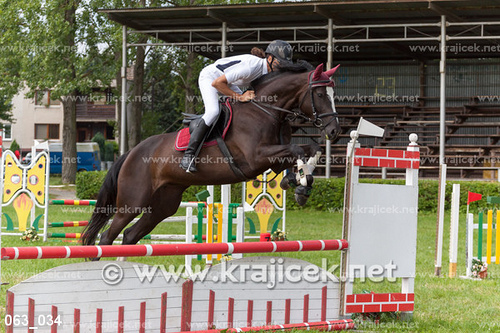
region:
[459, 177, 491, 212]
The flag is red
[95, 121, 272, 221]
The horse is dark brown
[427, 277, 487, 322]
The grass is green and long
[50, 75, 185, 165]
The trees are in the back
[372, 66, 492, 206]
The bleachers are empty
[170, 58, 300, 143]
The jockey has on white clothes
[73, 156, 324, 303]
The horse is jumping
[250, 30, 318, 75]
The jockey has a helmet on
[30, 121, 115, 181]
The van is parked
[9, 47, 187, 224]
Buildings are in the back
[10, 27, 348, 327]
horse and rider jumping over red pole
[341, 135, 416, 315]
white panel with bricks painted on top and bottom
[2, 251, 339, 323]
spaced red vertical lines on curved white panels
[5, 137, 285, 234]
yellow butterfly supports at end of poles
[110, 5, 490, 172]
dark roof and metal supports over wooden stands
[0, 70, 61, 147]
tan building with windows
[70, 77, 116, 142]
brown terrace over recessed entry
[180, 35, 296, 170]
rider in white outfit with black boots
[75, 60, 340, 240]
dark brown horse with covered red ears and red padding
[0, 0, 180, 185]
pale sky through tree branches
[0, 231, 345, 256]
a long red and white pole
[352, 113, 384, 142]
a small white flag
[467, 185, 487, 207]
a small red flag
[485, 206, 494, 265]
a tall yellow pole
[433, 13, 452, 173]
a tall gray pole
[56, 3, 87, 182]
a tall gray tree trunk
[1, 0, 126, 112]
green tree leaves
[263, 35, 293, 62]
a black helmet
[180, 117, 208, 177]
a woman's black boot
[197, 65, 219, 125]
the leg of a woman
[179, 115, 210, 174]
black boot on the rider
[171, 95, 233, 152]
black and red saddle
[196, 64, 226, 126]
white pants on the rider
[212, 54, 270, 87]
white and black shirt on the rider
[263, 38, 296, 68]
black helmet on the rider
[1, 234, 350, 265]
red jumping bar under the horse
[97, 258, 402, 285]
clear watermark logo across the photo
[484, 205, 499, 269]
yellow jump planks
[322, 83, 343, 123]
white mark on the horse's head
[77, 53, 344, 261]
brown horse with it's rider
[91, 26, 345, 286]
Large horse leaping in the air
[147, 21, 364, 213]
Small jokey on a horse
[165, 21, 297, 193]
Woman wearing riding boots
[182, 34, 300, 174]
Woman wearing black hat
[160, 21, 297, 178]
Woman wearing white shirt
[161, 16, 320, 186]
Woman wearing white pants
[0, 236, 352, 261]
Red and white pole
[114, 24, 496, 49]
Large metal posts on a buiolding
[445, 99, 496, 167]
Small section of bleachers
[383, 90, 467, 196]
Small section of bleachers